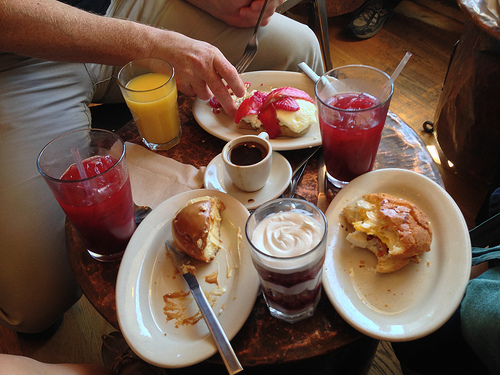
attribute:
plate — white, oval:
[320, 165, 473, 340]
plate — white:
[190, 68, 348, 152]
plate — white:
[115, 187, 262, 370]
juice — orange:
[123, 70, 181, 143]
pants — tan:
[2, 1, 325, 334]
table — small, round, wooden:
[64, 69, 443, 368]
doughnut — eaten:
[172, 197, 224, 263]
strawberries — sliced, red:
[236, 86, 313, 138]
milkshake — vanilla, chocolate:
[244, 197, 328, 323]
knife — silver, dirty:
[164, 236, 244, 373]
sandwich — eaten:
[342, 193, 433, 274]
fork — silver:
[233, 0, 268, 75]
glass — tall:
[36, 125, 139, 264]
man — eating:
[3, 1, 328, 343]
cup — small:
[220, 130, 274, 192]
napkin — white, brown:
[106, 138, 208, 211]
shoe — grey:
[347, 1, 393, 42]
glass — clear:
[243, 195, 327, 319]